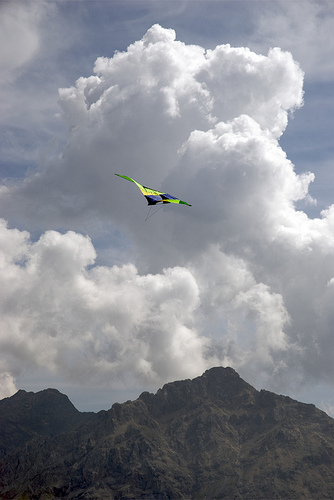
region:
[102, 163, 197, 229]
green and blue parasail in sky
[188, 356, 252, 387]
brown mountain top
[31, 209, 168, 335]
white cloud in blue sky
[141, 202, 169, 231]
dark parasail string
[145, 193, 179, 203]
strip purple in green parasail design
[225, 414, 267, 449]
low area in mountain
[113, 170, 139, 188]
green wing of parasail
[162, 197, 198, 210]
green wing of parasil with dark green top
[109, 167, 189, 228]
v shaped parasail in mid air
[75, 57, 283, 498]
parasail in mid air over mountains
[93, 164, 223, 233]
A kite is flying.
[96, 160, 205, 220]
The kite is green.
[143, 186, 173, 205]
The kite is blue.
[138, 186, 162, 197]
The kite is yellow.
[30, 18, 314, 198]
The sky is full of clouds.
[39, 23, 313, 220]
The clouds are fluffy.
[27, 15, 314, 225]
The clouds are white.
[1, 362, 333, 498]
A mountain is in the background.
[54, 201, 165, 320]
The kite's string is visible.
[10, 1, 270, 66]
The sky is blue.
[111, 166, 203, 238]
a big colorful kite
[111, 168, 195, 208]
The kite in the air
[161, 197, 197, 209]
The right wing of the kite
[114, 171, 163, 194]
The left wing of the kite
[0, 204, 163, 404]
The lines connected to the kite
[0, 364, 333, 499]
The large black mountain range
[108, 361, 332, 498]
The taller of the two mountain peaks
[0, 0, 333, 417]
The clouds above the mountain range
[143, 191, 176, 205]
The blue portion of the kite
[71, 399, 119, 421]
The low part between the mountain peaks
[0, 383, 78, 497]
The shorter of the two peaks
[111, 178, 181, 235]
a kite in the air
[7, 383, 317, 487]
the mountains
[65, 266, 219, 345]
the clouds in the sky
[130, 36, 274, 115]
light in the clouds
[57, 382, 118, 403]
the blue sky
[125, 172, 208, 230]
kite is different colors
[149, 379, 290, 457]
the mountain is dark brown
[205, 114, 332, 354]
the clouds are big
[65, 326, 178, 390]
a dark cloud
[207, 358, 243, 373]
tip of the mountain